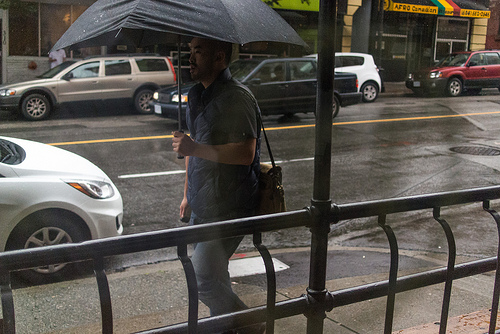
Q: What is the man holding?
A: An umbrella.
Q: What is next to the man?
A: A fence.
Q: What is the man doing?
A: Walking.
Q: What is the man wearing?
A: A satchel.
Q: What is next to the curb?
A: A SUV.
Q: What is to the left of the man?
A: Metal fencing.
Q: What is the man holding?
A: An umbrella.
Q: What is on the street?
A: A yellow line.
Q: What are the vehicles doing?
A: Parked.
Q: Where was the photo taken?
A: In a city.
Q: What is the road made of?
A: Asphalt.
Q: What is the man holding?
A: He's holding an umbrella.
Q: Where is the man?
A: He is on the sidewalk.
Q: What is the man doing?
A: He is walking holding an umbrella?.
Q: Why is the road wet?
A: It is raining.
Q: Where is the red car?
A: Parked on the side of the road.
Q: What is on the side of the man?
A: A black metal gate.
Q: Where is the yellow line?
A: In the middle of the road.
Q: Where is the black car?
A: Driving on the road.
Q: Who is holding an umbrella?
A: The man.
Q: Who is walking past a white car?
A: A man.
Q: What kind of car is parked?
A: Champagne color.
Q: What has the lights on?
A: The black car.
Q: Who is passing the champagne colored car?
A: The black car.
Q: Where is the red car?
A: In front of the shop.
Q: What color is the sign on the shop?
A: Yellow.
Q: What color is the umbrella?
A: Black.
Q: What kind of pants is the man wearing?
A: Jeans.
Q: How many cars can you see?
A: Five.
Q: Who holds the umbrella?
A: A man.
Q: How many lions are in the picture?
A: Zero.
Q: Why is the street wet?
A: It is raining.